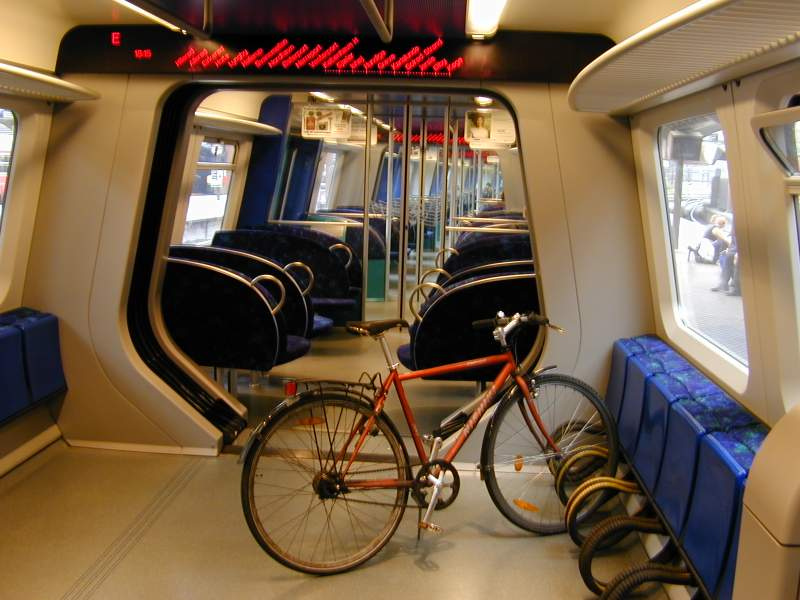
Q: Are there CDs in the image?
A: No, there are no cds.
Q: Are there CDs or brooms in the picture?
A: No, there are no CDs or brooms.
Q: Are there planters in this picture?
A: No, there are no planters.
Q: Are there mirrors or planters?
A: No, there are no planters or mirrors.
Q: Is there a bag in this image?
A: No, there are no bags.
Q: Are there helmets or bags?
A: No, there are no bags or helmets.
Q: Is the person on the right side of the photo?
A: Yes, the person is on the right of the image.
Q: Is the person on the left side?
A: No, the person is on the right of the image.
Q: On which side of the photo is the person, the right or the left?
A: The person is on the right of the image.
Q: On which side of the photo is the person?
A: The person is on the right of the image.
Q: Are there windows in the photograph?
A: Yes, there is a window.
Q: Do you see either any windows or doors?
A: Yes, there is a window.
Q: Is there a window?
A: Yes, there is a window.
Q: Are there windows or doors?
A: Yes, there is a window.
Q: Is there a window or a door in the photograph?
A: Yes, there is a window.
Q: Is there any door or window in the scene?
A: Yes, there is a window.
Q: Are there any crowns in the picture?
A: No, there are no crowns.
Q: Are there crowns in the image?
A: No, there are no crowns.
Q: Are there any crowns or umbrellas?
A: No, there are no crowns or umbrellas.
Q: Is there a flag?
A: No, there are no flags.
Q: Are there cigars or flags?
A: No, there are no flags or cigars.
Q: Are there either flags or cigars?
A: No, there are no flags or cigars.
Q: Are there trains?
A: Yes, there is a train.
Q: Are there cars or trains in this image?
A: Yes, there is a train.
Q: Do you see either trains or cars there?
A: Yes, there is a train.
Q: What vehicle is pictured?
A: The vehicle is a train.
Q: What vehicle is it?
A: The vehicle is a train.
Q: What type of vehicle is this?
A: That is a train.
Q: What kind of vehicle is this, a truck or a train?
A: That is a train.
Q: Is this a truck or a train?
A: This is a train.